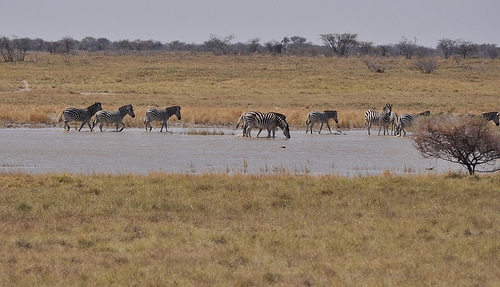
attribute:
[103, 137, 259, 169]
water — dark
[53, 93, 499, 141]
zebras — wading, walking, drinking, running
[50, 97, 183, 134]
zebras — running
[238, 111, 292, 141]
zebra — drinking, standing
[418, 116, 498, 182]
bush — growing, brown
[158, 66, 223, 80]
grass — dry, scorched, brown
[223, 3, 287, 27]
sky — gray, blue, hazy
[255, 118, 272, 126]
stripes — black, white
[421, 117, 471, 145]
tree — small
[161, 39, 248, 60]
day — hazy